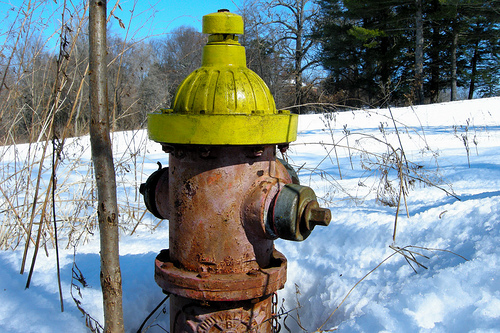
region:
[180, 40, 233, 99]
fire hydrant with yellow top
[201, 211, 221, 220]
fire hydrant in front of snow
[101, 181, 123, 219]
fire hydrant by thin tree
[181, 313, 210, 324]
stamped seal on hydrant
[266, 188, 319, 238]
arm on side of hydrant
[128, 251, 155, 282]
shadow cast in the snow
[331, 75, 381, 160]
thin branches sticking out of the snow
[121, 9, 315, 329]
this is a fire hydrant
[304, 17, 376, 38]
this is a branch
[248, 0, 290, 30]
this is a branch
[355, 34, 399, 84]
this is a branch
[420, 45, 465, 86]
this is a branch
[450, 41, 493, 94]
this is a branch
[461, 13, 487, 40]
this is a branch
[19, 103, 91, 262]
this is a branch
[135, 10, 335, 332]
a yellow rusted fire hydrant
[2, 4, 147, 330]
a tree by a fire hydrant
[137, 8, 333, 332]
a fire hydrant in the snow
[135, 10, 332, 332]
a fire hydrant by trees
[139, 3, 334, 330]
a fire hydrant surrounded by trees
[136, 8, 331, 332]
a fire hydrant in the woods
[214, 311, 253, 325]
the word VALVE on a fire hydrant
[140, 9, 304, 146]
the top yellow piece of a fire hydrant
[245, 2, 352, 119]
a tree with branches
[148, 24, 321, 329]
this is a hydrant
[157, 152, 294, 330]
the hydrant is metallic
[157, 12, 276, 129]
this is the top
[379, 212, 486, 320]
the snow is all over the place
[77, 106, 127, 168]
the tree is thin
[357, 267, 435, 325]
the snow is white in color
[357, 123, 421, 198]
these are the branches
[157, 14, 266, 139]
this is the top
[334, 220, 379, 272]
this is the snow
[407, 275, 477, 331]
the snow is white in color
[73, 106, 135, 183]
the tree is thin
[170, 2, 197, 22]
this is the sky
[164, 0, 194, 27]
the sky is blue in color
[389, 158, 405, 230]
brown branch in snow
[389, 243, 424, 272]
brown branch in snow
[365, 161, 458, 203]
brown branch in snow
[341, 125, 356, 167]
brown branch in snow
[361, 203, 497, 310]
Large body of snow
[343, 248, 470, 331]
Large body of snow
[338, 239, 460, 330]
Large body of snow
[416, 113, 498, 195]
Large body of snow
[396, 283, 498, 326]
Large body of snow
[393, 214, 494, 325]
Large body of snow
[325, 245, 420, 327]
Large body of snow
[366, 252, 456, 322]
Large body of snow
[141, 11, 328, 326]
red and yellow hydrant in white snow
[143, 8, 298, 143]
yellow top of hydrant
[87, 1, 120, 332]
thin stem of tree in left side of hydrant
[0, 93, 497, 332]
white snow in the ground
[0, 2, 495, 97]
light blue clear sky through trees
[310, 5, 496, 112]
trees with green leaves in the background in right side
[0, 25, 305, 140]
trees without in the background in left side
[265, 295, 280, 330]
rusty metal chains in red and yellow hydrant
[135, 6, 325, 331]
red and yellow hydrant in big forest coer with snow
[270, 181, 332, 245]
gray metal part of hydrant